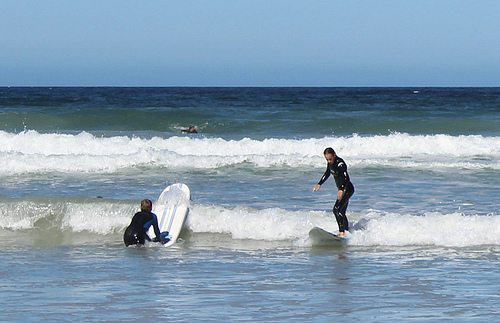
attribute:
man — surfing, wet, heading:
[118, 195, 168, 249]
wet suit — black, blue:
[123, 210, 161, 246]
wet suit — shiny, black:
[317, 157, 360, 234]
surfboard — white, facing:
[146, 177, 195, 249]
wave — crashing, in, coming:
[2, 126, 498, 172]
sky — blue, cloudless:
[1, 2, 499, 86]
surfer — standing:
[311, 136, 366, 237]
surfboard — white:
[306, 226, 349, 246]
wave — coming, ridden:
[2, 194, 497, 252]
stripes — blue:
[157, 184, 186, 232]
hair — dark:
[324, 147, 335, 153]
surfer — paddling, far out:
[179, 124, 203, 135]